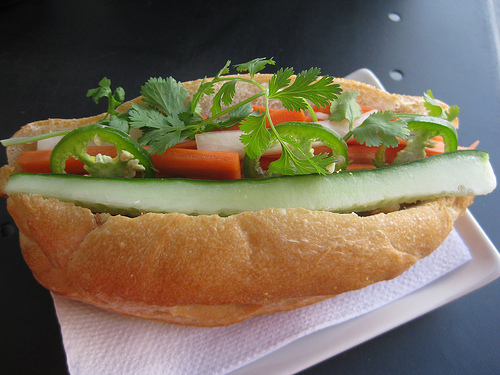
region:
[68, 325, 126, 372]
white napkin under sandwhich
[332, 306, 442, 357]
white ceramic square plate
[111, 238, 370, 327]
golden colored hoagie bread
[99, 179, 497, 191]
a slice of pickle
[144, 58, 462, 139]
cilantro leaves on sandwhich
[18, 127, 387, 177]
carrot slices inside sandwhich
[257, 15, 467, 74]
black table under sandwhich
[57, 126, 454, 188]
slices of jalepeno peppers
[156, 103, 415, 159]
long onion slices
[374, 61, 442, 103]
mall cut out holes on table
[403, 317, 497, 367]
the black table top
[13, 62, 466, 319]
the veggie sandwich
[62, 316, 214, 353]
the napkin under the sandwich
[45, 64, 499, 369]
the small white plate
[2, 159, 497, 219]
the cucumber slice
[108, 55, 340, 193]
the cilantro on the sandwich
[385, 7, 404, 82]
the holes in the table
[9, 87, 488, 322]
the bread cut in the middle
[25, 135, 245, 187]
the carrot in the sandwich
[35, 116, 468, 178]
the sliced green peppers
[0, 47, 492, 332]
a sandwich of vegetables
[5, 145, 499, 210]
slice of cucumber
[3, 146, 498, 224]
cucumber has green peel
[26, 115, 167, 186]
slice of pepper with seeds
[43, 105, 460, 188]
three slices of green ppepper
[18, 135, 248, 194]
slices of carrot on sandwich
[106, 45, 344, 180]
a bunch of parsley on top of sandwich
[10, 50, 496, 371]
sandwich on white napkin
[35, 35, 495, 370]
sandwich on a white dish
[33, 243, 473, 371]
napkin is white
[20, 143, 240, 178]
carrot on a sandwich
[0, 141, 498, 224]
a long piece of squash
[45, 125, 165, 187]
a slice of bell pepper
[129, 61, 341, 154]
sprigs of Italian parsley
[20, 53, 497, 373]
sandwich on a rectangular platter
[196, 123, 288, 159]
a piece of onion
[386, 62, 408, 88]
a fastener of some type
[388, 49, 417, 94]
the head of a nail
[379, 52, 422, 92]
a rivet in the table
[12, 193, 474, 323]
top of a sandwich bun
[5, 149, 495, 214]
a green cucumber cut long ways.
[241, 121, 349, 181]
jalapeno and cilantro on a sandwich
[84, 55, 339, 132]
fresh green cilantro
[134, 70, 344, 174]
cilantro, jalapeno, onion and carrots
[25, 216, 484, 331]
white bread sandwich roll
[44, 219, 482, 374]
a white napkin on a white plate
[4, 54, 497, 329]
a vegatable sandwich on white bread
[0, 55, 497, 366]
a spicy vegetable sandwich on a white napkins and plate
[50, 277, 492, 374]
a white napkin on a white ceramic plate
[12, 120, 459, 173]
a carrot and onion sandwich